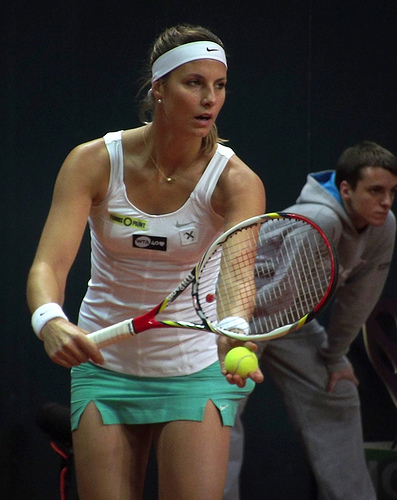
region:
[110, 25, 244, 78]
tennis player is wearing white headband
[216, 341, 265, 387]
yellow ball is in lady's hand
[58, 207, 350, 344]
red, yellow, black and white racquet is in lady's hand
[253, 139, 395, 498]
man in background is wearing gray track suit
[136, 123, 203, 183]
woman is wearing gold necklace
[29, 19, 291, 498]
athletic woman is playing tennis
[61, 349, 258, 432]
woman is wearing aqua skirt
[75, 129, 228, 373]
woman is wearing white sleeveless shirt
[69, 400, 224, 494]
woman's legs are bare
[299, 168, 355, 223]
inside of man's gray hood is blue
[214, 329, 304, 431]
A tennis ball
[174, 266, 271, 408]
A tennis ball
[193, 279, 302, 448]
A tennis ball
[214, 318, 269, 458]
A tennis ball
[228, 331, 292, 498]
A tennis ball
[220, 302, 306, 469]
A ball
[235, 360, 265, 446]
A ball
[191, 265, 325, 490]
A ball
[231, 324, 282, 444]
A ball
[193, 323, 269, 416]
A ball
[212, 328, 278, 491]
A ball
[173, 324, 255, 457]
A ball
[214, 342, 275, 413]
A tennis ball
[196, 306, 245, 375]
A tennis ball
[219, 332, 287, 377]
A tennis ball